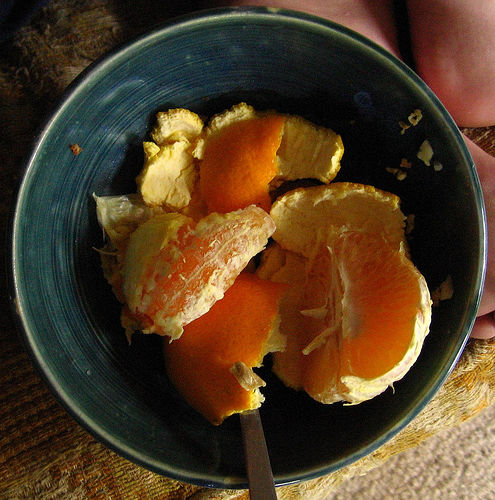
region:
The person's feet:
[243, 1, 493, 351]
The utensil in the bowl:
[239, 397, 284, 499]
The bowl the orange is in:
[9, 2, 489, 489]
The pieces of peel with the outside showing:
[169, 112, 286, 427]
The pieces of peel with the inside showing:
[139, 102, 404, 393]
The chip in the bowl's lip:
[265, 3, 283, 15]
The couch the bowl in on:
[2, 2, 494, 499]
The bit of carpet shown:
[292, 399, 494, 499]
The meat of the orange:
[109, 209, 434, 407]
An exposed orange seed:
[229, 355, 269, 392]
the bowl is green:
[5, 7, 492, 485]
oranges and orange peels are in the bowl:
[29, 26, 475, 413]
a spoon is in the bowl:
[213, 370, 284, 498]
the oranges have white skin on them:
[128, 199, 305, 329]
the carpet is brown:
[365, 445, 485, 492]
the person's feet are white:
[351, 0, 492, 346]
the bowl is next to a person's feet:
[3, 5, 487, 461]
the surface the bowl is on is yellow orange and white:
[257, 352, 474, 487]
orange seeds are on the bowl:
[46, 124, 119, 182]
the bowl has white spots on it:
[3, 64, 240, 432]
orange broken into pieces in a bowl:
[130, 105, 442, 436]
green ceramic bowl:
[77, 340, 134, 424]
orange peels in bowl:
[155, 110, 355, 190]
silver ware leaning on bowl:
[240, 373, 290, 497]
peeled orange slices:
[294, 225, 434, 418]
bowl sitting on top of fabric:
[20, 371, 121, 494]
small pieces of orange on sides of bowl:
[364, 104, 449, 188]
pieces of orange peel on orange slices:
[166, 218, 238, 279]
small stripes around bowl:
[60, 300, 114, 416]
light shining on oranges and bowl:
[377, 259, 464, 379]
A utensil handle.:
[227, 409, 289, 497]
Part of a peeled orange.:
[104, 187, 274, 317]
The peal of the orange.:
[155, 100, 342, 187]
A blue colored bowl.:
[4, 9, 490, 481]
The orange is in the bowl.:
[91, 121, 430, 419]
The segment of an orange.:
[333, 233, 420, 408]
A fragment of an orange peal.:
[186, 265, 281, 420]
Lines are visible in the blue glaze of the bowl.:
[13, 85, 94, 412]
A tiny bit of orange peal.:
[145, 101, 201, 135]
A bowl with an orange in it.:
[33, 43, 470, 488]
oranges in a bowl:
[173, 163, 339, 350]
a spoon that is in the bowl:
[229, 434, 284, 470]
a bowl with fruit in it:
[27, 116, 126, 400]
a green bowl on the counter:
[16, 213, 112, 396]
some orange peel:
[150, 121, 203, 206]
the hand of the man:
[415, 11, 477, 90]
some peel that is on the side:
[370, 118, 456, 197]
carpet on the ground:
[424, 447, 476, 495]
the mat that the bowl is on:
[1, 457, 146, 492]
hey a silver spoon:
[226, 433, 335, 496]